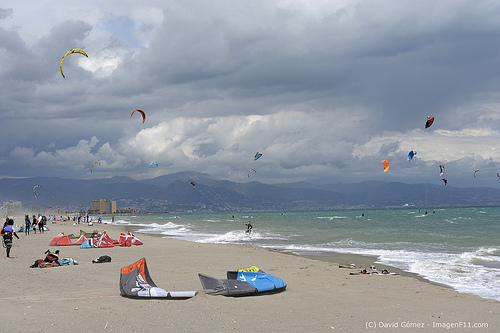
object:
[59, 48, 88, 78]
sail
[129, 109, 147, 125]
sail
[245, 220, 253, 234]
kitesurfing man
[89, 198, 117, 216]
buildings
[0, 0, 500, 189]
sky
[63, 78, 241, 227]
rope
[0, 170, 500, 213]
mountain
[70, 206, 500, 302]
ocean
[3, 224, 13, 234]
blue top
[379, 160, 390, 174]
kite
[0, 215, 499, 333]
beach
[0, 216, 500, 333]
shore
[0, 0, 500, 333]
background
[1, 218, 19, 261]
people